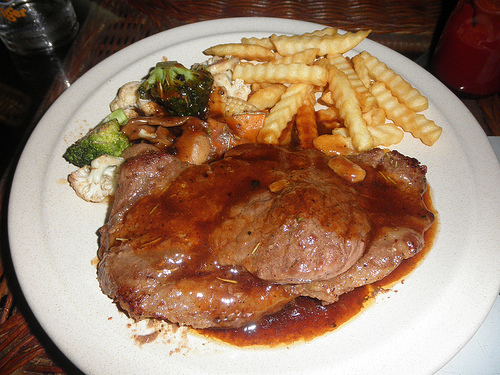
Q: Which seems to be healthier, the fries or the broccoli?
A: The broccoli is healthier than the fries.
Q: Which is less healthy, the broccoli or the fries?
A: The fries is less healthy than the broccoli.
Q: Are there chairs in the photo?
A: No, there are no chairs.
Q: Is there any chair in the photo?
A: No, there are no chairs.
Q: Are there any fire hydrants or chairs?
A: No, there are no chairs or fire hydrants.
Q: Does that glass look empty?
A: Yes, the glass is empty.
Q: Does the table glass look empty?
A: Yes, the glass is empty.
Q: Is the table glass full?
A: No, the glass is empty.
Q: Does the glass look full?
A: No, the glass is empty.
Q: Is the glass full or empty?
A: The glass is empty.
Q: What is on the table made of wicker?
A: The glass is on the table.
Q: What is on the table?
A: The glass is on the table.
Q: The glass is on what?
A: The glass is on the table.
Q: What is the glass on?
A: The glass is on the table.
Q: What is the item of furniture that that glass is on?
A: The piece of furniture is a table.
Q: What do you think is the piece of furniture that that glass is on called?
A: The piece of furniture is a table.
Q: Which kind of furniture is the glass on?
A: The glass is on the table.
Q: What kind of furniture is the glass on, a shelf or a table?
A: The glass is on a table.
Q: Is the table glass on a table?
A: Yes, the glass is on a table.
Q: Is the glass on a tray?
A: No, the glass is on a table.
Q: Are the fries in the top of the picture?
A: Yes, the fries are in the top of the image.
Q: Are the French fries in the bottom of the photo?
A: No, the French fries are in the top of the image.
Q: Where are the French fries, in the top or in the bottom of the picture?
A: The French fries are in the top of the image.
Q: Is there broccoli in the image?
A: Yes, there is broccoli.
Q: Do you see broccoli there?
A: Yes, there is broccoli.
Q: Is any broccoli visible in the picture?
A: Yes, there is broccoli.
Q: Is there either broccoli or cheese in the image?
A: Yes, there is broccoli.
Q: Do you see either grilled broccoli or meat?
A: Yes, there is grilled broccoli.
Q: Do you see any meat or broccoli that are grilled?
A: Yes, the broccoli is grilled.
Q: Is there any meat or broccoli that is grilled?
A: Yes, the broccoli is grilled.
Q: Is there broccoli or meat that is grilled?
A: Yes, the broccoli is grilled.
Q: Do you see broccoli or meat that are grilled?
A: Yes, the broccoli is grilled.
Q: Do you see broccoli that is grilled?
A: Yes, there is grilled broccoli.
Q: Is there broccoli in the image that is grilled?
A: Yes, there is broccoli that is grilled.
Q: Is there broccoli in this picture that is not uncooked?
A: Yes, there is grilled broccoli.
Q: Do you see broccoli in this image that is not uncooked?
A: Yes, there is grilled broccoli.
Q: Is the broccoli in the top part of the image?
A: Yes, the broccoli is in the top of the image.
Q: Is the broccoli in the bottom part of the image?
A: No, the broccoli is in the top of the image.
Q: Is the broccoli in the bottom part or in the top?
A: The broccoli is in the top of the image.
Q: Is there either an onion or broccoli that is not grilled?
A: No, there is broccoli but it is grilled.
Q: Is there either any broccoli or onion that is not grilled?
A: No, there is broccoli but it is grilled.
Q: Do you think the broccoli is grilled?
A: Yes, the broccoli is grilled.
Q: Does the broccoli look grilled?
A: Yes, the broccoli is grilled.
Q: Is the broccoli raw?
A: No, the broccoli is grilled.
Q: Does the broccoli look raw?
A: No, the broccoli is grilled.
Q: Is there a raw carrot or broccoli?
A: No, there is broccoli but it is grilled.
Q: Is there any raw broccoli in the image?
A: No, there is broccoli but it is grilled.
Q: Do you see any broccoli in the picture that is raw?
A: No, there is broccoli but it is grilled.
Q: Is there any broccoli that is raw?
A: No, there is broccoli but it is grilled.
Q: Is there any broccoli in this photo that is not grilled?
A: No, there is broccoli but it is grilled.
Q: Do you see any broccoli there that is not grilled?
A: No, there is broccoli but it is grilled.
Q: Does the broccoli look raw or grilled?
A: The broccoli is grilled.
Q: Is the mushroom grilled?
A: Yes, the mushroom is grilled.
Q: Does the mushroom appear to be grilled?
A: Yes, the mushroom is grilled.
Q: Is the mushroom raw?
A: No, the mushroom is grilled.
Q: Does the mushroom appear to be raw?
A: No, the mushroom is grilled.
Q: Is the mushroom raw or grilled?
A: The mushroom is grilled.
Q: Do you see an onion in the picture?
A: No, there are no onions.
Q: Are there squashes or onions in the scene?
A: No, there are no onions or squashes.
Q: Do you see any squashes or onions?
A: No, there are no onions or squashes.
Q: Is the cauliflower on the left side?
A: Yes, the cauliflower is on the left of the image.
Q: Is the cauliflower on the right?
A: No, the cauliflower is on the left of the image.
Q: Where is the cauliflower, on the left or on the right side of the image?
A: The cauliflower is on the left of the image.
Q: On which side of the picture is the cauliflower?
A: The cauliflower is on the left of the image.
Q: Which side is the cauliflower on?
A: The cauliflower is on the left of the image.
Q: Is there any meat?
A: Yes, there is meat.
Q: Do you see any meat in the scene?
A: Yes, there is meat.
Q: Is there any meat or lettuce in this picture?
A: Yes, there is meat.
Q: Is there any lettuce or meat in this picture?
A: Yes, there is meat.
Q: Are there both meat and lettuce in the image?
A: No, there is meat but no lettuce.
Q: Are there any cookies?
A: No, there are no cookies.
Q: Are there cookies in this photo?
A: No, there are no cookies.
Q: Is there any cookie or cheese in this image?
A: No, there are no cookies or cheese.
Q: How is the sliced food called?
A: The food is meat.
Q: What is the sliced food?
A: The food is meat.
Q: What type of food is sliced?
A: The food is meat.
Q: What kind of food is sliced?
A: The food is meat.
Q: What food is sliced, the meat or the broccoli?
A: The meat is sliced.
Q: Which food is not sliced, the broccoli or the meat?
A: The broccoli is not sliced.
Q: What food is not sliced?
A: The food is broccoli.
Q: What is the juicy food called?
A: The food is meat.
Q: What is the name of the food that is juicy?
A: The food is meat.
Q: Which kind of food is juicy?
A: The food is meat.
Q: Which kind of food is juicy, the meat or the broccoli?
A: The meat is juicy.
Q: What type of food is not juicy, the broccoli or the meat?
A: The broccoli is not juicy.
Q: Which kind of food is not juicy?
A: The food is broccoli.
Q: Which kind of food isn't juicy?
A: The food is broccoli.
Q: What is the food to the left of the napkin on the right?
A: The food is meat.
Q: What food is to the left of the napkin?
A: The food is meat.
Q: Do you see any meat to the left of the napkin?
A: Yes, there is meat to the left of the napkin.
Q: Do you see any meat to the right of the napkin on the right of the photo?
A: No, the meat is to the left of the napkin.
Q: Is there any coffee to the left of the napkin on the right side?
A: No, there is meat to the left of the napkin.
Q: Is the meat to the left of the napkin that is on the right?
A: Yes, the meat is to the left of the napkin.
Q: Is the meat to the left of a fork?
A: No, the meat is to the left of the napkin.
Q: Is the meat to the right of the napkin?
A: No, the meat is to the left of the napkin.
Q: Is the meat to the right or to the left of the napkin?
A: The meat is to the left of the napkin.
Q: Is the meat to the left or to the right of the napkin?
A: The meat is to the left of the napkin.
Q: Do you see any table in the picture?
A: Yes, there is a table.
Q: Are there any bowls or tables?
A: Yes, there is a table.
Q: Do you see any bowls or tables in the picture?
A: Yes, there is a table.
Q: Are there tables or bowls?
A: Yes, there is a table.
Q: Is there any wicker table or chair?
A: Yes, there is a wicker table.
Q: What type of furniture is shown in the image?
A: The furniture is a table.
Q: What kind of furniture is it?
A: The piece of furniture is a table.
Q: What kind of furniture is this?
A: That is a table.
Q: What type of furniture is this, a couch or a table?
A: That is a table.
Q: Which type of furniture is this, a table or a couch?
A: That is a table.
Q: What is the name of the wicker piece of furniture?
A: The piece of furniture is a table.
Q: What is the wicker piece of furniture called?
A: The piece of furniture is a table.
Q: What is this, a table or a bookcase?
A: This is a table.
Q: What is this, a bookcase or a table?
A: This is a table.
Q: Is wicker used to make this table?
A: Yes, the table is made of wicker.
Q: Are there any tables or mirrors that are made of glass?
A: No, there is a table but it is made of wicker.